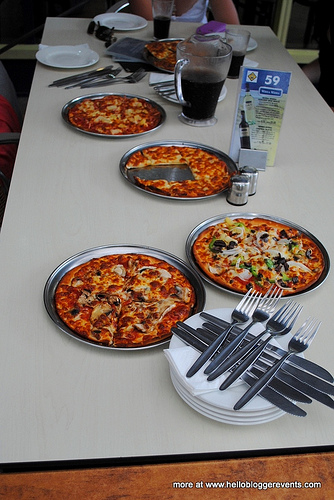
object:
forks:
[171, 281, 333, 416]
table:
[0, 15, 334, 470]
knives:
[170, 312, 333, 416]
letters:
[172, 481, 322, 488]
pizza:
[54, 253, 195, 347]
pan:
[43, 243, 206, 351]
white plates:
[169, 306, 304, 426]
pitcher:
[174, 34, 233, 127]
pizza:
[124, 144, 230, 197]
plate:
[35, 44, 98, 69]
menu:
[229, 67, 293, 167]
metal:
[184, 283, 321, 410]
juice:
[174, 68, 227, 120]